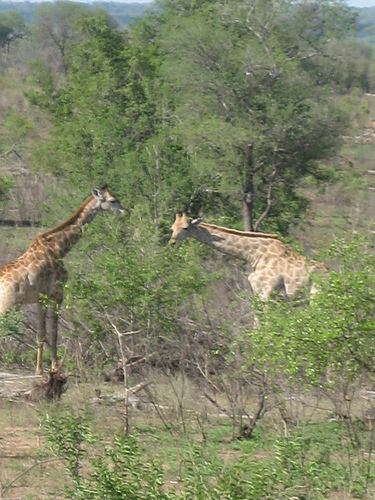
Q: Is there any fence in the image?
A: No, there are no fences.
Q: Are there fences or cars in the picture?
A: No, there are no fences or cars.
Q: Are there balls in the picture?
A: No, there are no balls.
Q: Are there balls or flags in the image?
A: No, there are no balls or flags.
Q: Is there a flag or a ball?
A: No, there are no balls or flags.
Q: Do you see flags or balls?
A: No, there are no balls or flags.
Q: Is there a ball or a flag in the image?
A: No, there are no balls or flags.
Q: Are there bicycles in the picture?
A: No, there are no bicycles.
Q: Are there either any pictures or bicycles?
A: No, there are no bicycles or pictures.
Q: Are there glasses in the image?
A: No, there are no glasses.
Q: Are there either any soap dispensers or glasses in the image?
A: No, there are no glasses or soap dispensers.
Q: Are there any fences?
A: No, there are no fences.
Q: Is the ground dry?
A: Yes, the ground is dry.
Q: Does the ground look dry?
A: Yes, the ground is dry.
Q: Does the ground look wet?
A: No, the ground is dry.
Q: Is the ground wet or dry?
A: The ground is dry.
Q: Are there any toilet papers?
A: No, there are no toilet papers.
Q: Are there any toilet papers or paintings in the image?
A: No, there are no toilet papers or paintings.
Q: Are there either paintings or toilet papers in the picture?
A: No, there are no toilet papers or paintings.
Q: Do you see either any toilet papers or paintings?
A: No, there are no toilet papers or paintings.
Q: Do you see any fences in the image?
A: No, there are no fences.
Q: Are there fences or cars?
A: No, there are no fences or cars.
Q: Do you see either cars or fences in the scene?
A: No, there are no fences or cars.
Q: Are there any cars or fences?
A: No, there are no fences or cars.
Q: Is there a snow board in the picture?
A: No, there are no snowboards.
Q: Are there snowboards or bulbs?
A: No, there are no snowboards or bulbs.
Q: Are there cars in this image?
A: No, there are no cars.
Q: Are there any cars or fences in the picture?
A: No, there are no cars or fences.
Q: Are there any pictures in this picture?
A: No, there are no pictures.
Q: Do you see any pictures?
A: No, there are no pictures.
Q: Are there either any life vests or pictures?
A: No, there are no pictures or life vests.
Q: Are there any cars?
A: No, there are no cars.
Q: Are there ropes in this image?
A: No, there are no ropes.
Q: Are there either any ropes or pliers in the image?
A: No, there are no ropes or pliers.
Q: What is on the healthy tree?
A: The leaves are on the tree.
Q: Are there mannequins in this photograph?
A: No, there are no mannequins.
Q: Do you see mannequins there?
A: No, there are no mannequins.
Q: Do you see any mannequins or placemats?
A: No, there are no mannequins or placemats.